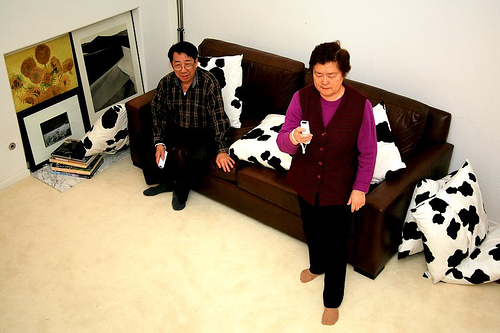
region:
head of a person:
[310, 31, 348, 98]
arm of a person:
[349, 99, 387, 193]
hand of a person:
[342, 195, 382, 216]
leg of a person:
[323, 212, 360, 312]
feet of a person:
[317, 315, 352, 330]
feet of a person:
[303, 262, 333, 289]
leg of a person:
[295, 205, 326, 257]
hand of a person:
[290, 121, 324, 151]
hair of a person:
[307, 43, 349, 61]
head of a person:
[155, 46, 200, 91]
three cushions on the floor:
[397, 152, 498, 294]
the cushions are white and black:
[390, 158, 498, 293]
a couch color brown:
[107, 28, 467, 293]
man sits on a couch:
[116, 17, 290, 219]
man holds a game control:
[131, 34, 238, 219]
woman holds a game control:
[271, 31, 381, 330]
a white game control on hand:
[291, 112, 314, 157]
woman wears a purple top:
[268, 33, 387, 329]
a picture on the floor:
[11, 78, 93, 184]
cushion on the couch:
[228, 88, 291, 180]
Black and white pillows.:
[395, 152, 497, 288]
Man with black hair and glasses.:
[160, 37, 205, 87]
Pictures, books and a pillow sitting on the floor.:
[0, 0, 125, 200]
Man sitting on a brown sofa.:
[130, 20, 270, 245]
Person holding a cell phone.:
[271, 32, 381, 217]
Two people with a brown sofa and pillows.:
[135, 25, 495, 330]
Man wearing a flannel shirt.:
[146, 35, 237, 175]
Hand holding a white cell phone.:
[287, 116, 320, 156]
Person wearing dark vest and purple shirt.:
[271, 35, 390, 224]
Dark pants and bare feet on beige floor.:
[281, 194, 346, 332]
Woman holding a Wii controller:
[276, 35, 380, 323]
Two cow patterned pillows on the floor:
[397, 155, 499, 288]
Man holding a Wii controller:
[141, 38, 236, 210]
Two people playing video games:
[142, 38, 379, 327]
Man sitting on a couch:
[137, 40, 235, 210]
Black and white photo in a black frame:
[15, 85, 92, 172]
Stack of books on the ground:
[48, 137, 102, 183]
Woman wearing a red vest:
[274, 40, 380, 325]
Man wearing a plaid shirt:
[139, 40, 235, 215]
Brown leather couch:
[122, 37, 454, 280]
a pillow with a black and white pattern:
[180, 54, 251, 130]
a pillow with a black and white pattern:
[225, 99, 318, 177]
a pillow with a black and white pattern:
[325, 101, 413, 190]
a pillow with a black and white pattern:
[70, 92, 157, 162]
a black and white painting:
[16, 86, 101, 177]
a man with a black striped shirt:
[142, 61, 237, 163]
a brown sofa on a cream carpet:
[116, 24, 455, 279]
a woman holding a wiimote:
[289, 120, 314, 154]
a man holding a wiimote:
[150, 146, 173, 171]